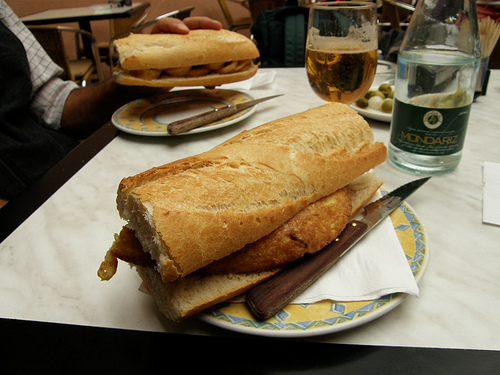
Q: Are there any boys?
A: No, there are no boys.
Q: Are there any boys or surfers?
A: No, there are no boys or surfers.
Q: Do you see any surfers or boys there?
A: No, there are no boys or surfers.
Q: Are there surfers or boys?
A: No, there are no boys or surfers.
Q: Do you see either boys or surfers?
A: No, there are no boys or surfers.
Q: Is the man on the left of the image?
A: Yes, the man is on the left of the image.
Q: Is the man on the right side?
A: No, the man is on the left of the image.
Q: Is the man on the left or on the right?
A: The man is on the left of the image.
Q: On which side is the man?
A: The man is on the left of the image.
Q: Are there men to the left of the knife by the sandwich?
A: Yes, there is a man to the left of the knife.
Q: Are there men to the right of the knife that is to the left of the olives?
A: No, the man is to the left of the knife.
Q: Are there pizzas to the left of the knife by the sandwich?
A: No, there is a man to the left of the knife.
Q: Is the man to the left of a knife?
A: Yes, the man is to the left of a knife.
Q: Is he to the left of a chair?
A: No, the man is to the left of a knife.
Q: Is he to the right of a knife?
A: No, the man is to the left of a knife.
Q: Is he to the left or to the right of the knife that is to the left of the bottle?
A: The man is to the left of the knife.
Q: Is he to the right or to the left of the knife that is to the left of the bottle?
A: The man is to the left of the knife.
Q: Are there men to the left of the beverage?
A: Yes, there is a man to the left of the beverage.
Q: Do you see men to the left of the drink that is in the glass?
A: Yes, there is a man to the left of the beverage.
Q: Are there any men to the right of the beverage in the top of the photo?
A: No, the man is to the left of the beverage.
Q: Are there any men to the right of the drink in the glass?
A: No, the man is to the left of the beverage.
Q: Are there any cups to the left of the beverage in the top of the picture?
A: No, there is a man to the left of the beverage.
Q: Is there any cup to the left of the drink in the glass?
A: No, there is a man to the left of the beverage.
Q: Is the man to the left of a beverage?
A: Yes, the man is to the left of a beverage.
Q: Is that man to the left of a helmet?
A: No, the man is to the left of a beverage.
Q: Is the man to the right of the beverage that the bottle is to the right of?
A: No, the man is to the left of the beverage.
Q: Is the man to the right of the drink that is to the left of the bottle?
A: No, the man is to the left of the beverage.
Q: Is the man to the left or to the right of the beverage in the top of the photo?
A: The man is to the left of the beverage.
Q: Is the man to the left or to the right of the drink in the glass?
A: The man is to the left of the beverage.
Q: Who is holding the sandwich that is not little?
A: The man is holding the sandwich.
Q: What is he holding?
A: The man is holding the sandwich.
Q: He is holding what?
A: The man is holding the sandwich.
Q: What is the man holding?
A: The man is holding the sandwich.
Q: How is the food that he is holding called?
A: The food is a sandwich.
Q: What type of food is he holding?
A: The man is holding the sandwich.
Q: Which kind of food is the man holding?
A: The man is holding the sandwich.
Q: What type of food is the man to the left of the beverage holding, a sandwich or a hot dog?
A: The man is holding a sandwich.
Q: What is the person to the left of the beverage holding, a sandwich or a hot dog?
A: The man is holding a sandwich.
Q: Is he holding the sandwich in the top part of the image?
A: Yes, the man is holding the sandwich.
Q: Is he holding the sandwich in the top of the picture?
A: Yes, the man is holding the sandwich.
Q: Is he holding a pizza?
A: No, the man is holding the sandwich.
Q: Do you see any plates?
A: Yes, there is a plate.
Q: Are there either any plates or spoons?
A: Yes, there is a plate.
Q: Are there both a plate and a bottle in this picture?
A: Yes, there are both a plate and a bottle.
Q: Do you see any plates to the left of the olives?
A: Yes, there is a plate to the left of the olives.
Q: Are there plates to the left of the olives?
A: Yes, there is a plate to the left of the olives.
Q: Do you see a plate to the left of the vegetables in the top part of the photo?
A: Yes, there is a plate to the left of the olives.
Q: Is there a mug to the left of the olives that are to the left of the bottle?
A: No, there is a plate to the left of the olives.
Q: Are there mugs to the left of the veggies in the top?
A: No, there is a plate to the left of the olives.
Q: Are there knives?
A: Yes, there is a knife.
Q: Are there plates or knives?
A: Yes, there is a knife.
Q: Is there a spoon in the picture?
A: No, there are no spoons.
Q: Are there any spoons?
A: No, there are no spoons.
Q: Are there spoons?
A: No, there are no spoons.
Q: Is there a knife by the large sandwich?
A: Yes, there is a knife by the sandwich.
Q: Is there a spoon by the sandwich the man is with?
A: No, there is a knife by the sandwich.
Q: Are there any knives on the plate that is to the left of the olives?
A: Yes, there is a knife on the plate.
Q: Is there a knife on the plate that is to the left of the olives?
A: Yes, there is a knife on the plate.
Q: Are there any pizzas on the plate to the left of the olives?
A: No, there is a knife on the plate.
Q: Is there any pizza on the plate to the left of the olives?
A: No, there is a knife on the plate.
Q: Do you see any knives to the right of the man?
A: Yes, there is a knife to the right of the man.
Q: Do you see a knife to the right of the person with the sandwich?
A: Yes, there is a knife to the right of the man.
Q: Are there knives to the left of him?
A: No, the knife is to the right of the man.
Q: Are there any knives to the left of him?
A: No, the knife is to the right of the man.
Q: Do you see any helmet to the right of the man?
A: No, there is a knife to the right of the man.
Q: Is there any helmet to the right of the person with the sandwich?
A: No, there is a knife to the right of the man.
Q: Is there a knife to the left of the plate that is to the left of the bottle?
A: Yes, there is a knife to the left of the plate.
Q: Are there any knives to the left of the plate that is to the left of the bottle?
A: Yes, there is a knife to the left of the plate.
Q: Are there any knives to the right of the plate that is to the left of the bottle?
A: No, the knife is to the left of the plate.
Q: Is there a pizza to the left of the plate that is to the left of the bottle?
A: No, there is a knife to the left of the plate.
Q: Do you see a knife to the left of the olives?
A: Yes, there is a knife to the left of the olives.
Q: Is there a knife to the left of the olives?
A: Yes, there is a knife to the left of the olives.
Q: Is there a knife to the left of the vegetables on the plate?
A: Yes, there is a knife to the left of the olives.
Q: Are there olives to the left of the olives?
A: No, there is a knife to the left of the olives.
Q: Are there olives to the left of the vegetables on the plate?
A: No, there is a knife to the left of the olives.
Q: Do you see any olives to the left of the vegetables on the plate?
A: No, there is a knife to the left of the olives.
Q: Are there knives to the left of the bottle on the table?
A: Yes, there is a knife to the left of the bottle.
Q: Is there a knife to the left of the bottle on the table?
A: Yes, there is a knife to the left of the bottle.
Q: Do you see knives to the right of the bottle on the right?
A: No, the knife is to the left of the bottle.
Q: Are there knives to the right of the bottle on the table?
A: No, the knife is to the left of the bottle.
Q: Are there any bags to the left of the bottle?
A: No, there is a knife to the left of the bottle.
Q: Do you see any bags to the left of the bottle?
A: No, there is a knife to the left of the bottle.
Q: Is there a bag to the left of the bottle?
A: No, there is a knife to the left of the bottle.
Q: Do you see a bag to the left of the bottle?
A: No, there is a knife to the left of the bottle.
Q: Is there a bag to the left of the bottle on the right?
A: No, there is a knife to the left of the bottle.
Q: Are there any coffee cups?
A: No, there are no coffee cups.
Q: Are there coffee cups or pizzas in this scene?
A: No, there are no coffee cups or pizzas.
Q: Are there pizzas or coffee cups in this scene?
A: No, there are no coffee cups or pizzas.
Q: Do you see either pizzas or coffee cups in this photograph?
A: No, there are no coffee cups or pizzas.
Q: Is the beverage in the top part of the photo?
A: Yes, the beverage is in the top of the image.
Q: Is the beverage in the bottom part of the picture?
A: No, the beverage is in the top of the image.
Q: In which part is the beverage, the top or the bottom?
A: The beverage is in the top of the image.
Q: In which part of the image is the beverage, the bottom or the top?
A: The beverage is in the top of the image.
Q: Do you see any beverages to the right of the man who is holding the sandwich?
A: Yes, there is a beverage to the right of the man.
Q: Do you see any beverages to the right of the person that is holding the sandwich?
A: Yes, there is a beverage to the right of the man.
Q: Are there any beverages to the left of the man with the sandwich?
A: No, the beverage is to the right of the man.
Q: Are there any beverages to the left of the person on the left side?
A: No, the beverage is to the right of the man.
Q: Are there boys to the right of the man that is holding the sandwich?
A: No, there is a beverage to the right of the man.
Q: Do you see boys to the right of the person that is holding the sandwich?
A: No, there is a beverage to the right of the man.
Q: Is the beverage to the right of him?
A: Yes, the beverage is to the right of a man.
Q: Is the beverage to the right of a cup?
A: No, the beverage is to the right of a man.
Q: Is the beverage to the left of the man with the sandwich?
A: No, the beverage is to the right of the man.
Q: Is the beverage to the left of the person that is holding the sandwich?
A: No, the beverage is to the right of the man.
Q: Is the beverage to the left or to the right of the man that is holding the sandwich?
A: The beverage is to the right of the man.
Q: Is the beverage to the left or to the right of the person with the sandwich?
A: The beverage is to the right of the man.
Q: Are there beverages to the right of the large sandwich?
A: Yes, there is a beverage to the right of the sandwich.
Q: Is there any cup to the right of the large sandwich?
A: No, there is a beverage to the right of the sandwich.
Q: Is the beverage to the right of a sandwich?
A: Yes, the beverage is to the right of a sandwich.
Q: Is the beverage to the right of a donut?
A: No, the beverage is to the right of a sandwich.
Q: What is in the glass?
A: The beverage is in the glass.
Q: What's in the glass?
A: The beverage is in the glass.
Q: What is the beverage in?
A: The beverage is in the glass.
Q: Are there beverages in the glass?
A: Yes, there is a beverage in the glass.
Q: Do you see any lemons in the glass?
A: No, there is a beverage in the glass.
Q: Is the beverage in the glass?
A: Yes, the beverage is in the glass.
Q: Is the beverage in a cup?
A: No, the beverage is in the glass.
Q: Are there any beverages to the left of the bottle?
A: Yes, there is a beverage to the left of the bottle.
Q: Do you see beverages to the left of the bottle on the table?
A: Yes, there is a beverage to the left of the bottle.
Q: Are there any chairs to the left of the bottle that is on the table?
A: No, there is a beverage to the left of the bottle.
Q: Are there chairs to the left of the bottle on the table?
A: No, there is a beverage to the left of the bottle.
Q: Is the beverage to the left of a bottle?
A: Yes, the beverage is to the left of a bottle.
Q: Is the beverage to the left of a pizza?
A: No, the beverage is to the left of a bottle.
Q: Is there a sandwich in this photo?
A: Yes, there is a sandwich.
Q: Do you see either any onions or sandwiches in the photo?
A: Yes, there is a sandwich.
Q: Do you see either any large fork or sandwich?
A: Yes, there is a large sandwich.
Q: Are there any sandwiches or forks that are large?
A: Yes, the sandwich is large.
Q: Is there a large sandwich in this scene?
A: Yes, there is a large sandwich.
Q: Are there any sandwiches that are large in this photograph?
A: Yes, there is a large sandwich.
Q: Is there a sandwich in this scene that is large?
A: Yes, there is a sandwich that is large.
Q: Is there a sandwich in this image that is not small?
A: Yes, there is a large sandwich.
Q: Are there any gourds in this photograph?
A: No, there are no gourds.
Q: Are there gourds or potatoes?
A: No, there are no gourds or potatoes.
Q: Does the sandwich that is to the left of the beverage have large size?
A: Yes, the sandwich is large.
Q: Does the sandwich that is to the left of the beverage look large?
A: Yes, the sandwich is large.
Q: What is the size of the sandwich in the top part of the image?
A: The sandwich is large.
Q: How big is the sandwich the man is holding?
A: The sandwich is large.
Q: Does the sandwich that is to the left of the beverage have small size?
A: No, the sandwich is large.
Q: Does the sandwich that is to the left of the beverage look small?
A: No, the sandwich is large.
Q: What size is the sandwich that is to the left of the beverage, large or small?
A: The sandwich is large.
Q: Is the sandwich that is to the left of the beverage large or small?
A: The sandwich is large.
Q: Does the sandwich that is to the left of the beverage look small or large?
A: The sandwich is large.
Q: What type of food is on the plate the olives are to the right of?
A: The food is a sandwich.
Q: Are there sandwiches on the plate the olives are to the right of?
A: Yes, there is a sandwich on the plate.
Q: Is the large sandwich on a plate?
A: Yes, the sandwich is on a plate.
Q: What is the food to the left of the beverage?
A: The food is a sandwich.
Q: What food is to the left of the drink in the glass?
A: The food is a sandwich.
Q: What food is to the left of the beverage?
A: The food is a sandwich.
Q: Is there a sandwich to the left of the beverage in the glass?
A: Yes, there is a sandwich to the left of the beverage.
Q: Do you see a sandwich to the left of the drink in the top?
A: Yes, there is a sandwich to the left of the beverage.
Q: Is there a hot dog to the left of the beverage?
A: No, there is a sandwich to the left of the beverage.